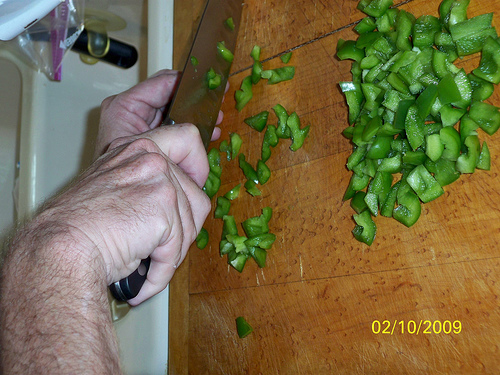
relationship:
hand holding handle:
[25, 64, 216, 308] [106, 114, 206, 300]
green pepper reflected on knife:
[332, 1, 498, 246] [105, 1, 245, 301]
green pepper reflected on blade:
[332, 1, 498, 246] [165, 0, 243, 153]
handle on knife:
[99, 254, 159, 309] [104, 7, 232, 310]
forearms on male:
[1, 105, 165, 372] [2, 65, 214, 375]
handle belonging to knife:
[99, 254, 159, 309] [161, 0, 243, 154]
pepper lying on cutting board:
[464, 99, 496, 133] [161, 2, 496, 370]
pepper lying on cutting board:
[435, 74, 472, 109] [161, 2, 496, 370]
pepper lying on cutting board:
[451, 12, 498, 61] [161, 2, 496, 370]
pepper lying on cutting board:
[404, 164, 446, 204] [161, 2, 496, 370]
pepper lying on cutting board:
[390, 186, 425, 226] [161, 2, 496, 370]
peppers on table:
[344, 24, 492, 196] [169, 1, 499, 373]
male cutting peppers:
[2, 65, 214, 375] [318, 3, 496, 245]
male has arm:
[2, 65, 214, 375] [0, 219, 130, 373]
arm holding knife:
[0, 219, 130, 373] [105, 1, 245, 301]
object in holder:
[25, 24, 146, 74] [49, 4, 131, 71]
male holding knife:
[2, 65, 214, 375] [89, 17, 306, 303]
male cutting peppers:
[2, 65, 214, 355] [208, 2, 498, 274]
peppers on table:
[208, 2, 498, 274] [169, 1, 499, 373]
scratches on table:
[296, 256, 305, 286] [169, 1, 499, 373]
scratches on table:
[252, 267, 268, 284] [169, 1, 499, 373]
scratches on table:
[224, 263, 231, 273] [169, 1, 499, 373]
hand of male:
[0, 110, 219, 300] [2, 65, 214, 375]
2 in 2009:
[423, 318, 432, 335] [423, 318, 461, 333]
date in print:
[369, 316, 461, 338] [361, 306, 484, 345]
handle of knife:
[99, 254, 159, 309] [105, 1, 245, 301]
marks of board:
[359, 271, 427, 304] [163, 0, 498, 374]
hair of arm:
[14, 258, 93, 318] [2, 75, 235, 370]